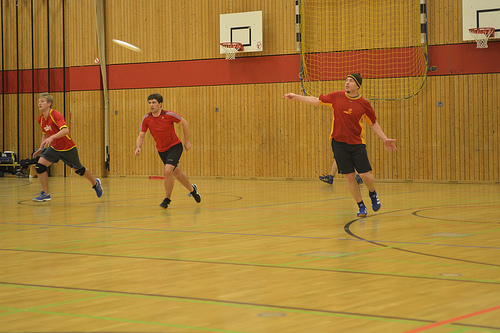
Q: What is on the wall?
A: A hoop.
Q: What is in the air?
A: Frisbee.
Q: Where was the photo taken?
A: In a gym.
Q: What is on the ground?
A: Lines.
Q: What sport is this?
A: Frisbee.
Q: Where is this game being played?
A: Gym.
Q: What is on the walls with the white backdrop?
A: Basketball hoop.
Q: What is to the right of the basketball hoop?
A: Net.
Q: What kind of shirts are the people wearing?
A: Red short sleeve t-shirt.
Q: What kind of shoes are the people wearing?
A: Sneakers.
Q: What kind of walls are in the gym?
A: Wood panelled walls.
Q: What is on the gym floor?
A: Green, black and orange lines.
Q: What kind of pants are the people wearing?
A: Black shorts.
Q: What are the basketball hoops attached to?
A: White boards.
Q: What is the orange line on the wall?
A: A stripe.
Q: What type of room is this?
A: A gymnasium?.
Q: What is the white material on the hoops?
A: Basketball nets.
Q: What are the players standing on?
A: A hardwood floor.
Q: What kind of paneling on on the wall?
A: Wood paneling.